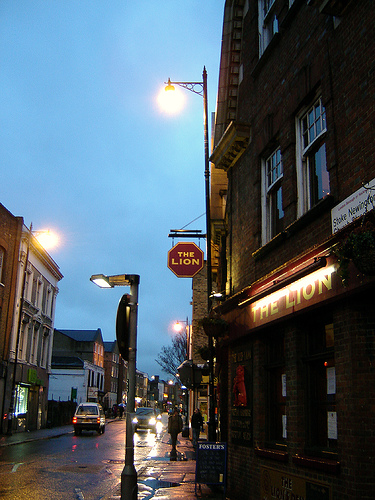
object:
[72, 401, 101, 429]
back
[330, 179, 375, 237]
sign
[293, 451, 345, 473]
sill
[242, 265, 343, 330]
sign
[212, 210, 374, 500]
restaurant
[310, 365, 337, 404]
windows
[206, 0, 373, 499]
apartment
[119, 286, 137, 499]
pole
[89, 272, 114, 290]
light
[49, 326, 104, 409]
building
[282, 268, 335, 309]
word lion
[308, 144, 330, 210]
window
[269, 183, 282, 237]
window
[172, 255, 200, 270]
writing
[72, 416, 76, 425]
lights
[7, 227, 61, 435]
street lamp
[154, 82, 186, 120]
street light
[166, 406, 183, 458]
person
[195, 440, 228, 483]
sign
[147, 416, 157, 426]
headlight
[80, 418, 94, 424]
licence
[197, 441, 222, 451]
lettering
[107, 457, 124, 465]
manhole lid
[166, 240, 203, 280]
sign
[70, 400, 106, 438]
car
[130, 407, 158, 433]
car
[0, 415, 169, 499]
road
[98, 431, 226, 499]
sidewalk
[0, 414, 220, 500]
ground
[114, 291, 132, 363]
sign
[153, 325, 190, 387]
tree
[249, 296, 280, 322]
word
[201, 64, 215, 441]
lamp post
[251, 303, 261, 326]
letter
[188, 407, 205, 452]
person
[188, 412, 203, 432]
sweater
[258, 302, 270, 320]
letter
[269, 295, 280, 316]
letter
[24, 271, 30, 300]
window